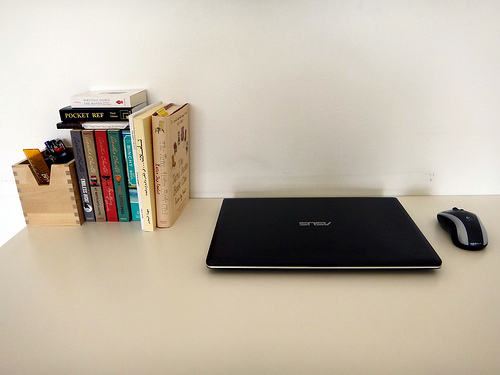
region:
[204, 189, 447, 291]
the laptop is closed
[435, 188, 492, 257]
the mouse is on the table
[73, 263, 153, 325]
the table is tan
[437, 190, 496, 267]
the mouse is black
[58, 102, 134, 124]
the laptop is black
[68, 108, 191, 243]
the books are on the table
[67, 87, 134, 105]
is book is white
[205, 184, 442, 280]
the book is black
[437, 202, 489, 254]
the mouse is silver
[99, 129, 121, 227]
the book is red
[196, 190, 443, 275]
a closed laptop computer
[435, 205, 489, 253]
a black and grey mouse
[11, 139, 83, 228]
a wooden desk container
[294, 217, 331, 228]
ASUS corporate logo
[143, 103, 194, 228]
a brown hard back book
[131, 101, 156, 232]
a yellow hard back book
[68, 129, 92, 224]
a purple hard back book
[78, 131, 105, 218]
a brown hard back book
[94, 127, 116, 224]
a red hard back book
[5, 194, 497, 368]
a light tan desk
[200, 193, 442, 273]
Black laptop on beige table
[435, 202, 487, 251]
Black and gray mouse next to black laptop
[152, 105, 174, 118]
Yellow bookmark in book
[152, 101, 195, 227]
Book standing in front of another book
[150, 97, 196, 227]
Book near black laptop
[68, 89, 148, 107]
Small white book on top of black book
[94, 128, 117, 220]
Red book next to green book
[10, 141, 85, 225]
Wooden square box holding ruler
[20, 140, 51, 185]
Ruler is orange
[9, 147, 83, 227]
Wooden square box on beige table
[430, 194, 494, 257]
computer mouse on a desk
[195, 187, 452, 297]
laptop on a desk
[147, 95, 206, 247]
book on a desk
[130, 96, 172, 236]
book on a desk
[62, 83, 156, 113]
book on a desk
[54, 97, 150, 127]
book on a desk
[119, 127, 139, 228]
book on a desk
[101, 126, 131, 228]
book on a desk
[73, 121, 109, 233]
book on a desk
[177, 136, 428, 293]
a laptop closed on a table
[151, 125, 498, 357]
a black laptop on the table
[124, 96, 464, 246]
an asus black laptop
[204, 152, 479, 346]
an asus closed laptop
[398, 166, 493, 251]
a black and silver mouse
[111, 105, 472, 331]
a laptop and mouse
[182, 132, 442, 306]
a black laptop and mouse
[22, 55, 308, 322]
books standing on table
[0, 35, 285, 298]
books stacked on table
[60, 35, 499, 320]
books and laptop on table